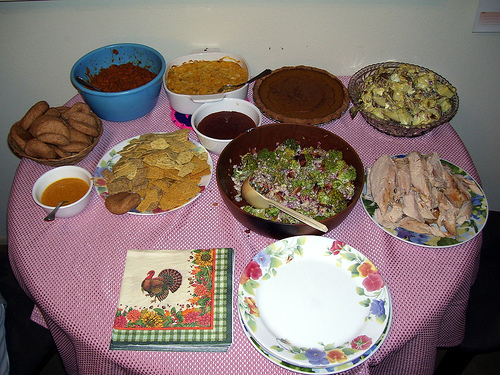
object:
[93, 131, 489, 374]
plate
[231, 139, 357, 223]
flowers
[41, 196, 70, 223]
spoon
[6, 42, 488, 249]
food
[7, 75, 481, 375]
table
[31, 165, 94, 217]
cup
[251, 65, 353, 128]
pie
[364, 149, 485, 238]
meat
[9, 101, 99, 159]
roll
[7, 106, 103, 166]
basket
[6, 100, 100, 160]
bread rolls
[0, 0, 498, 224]
wall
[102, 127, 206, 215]
cracker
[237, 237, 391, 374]
flowers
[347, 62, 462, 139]
dish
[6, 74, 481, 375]
cloth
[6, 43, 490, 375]
bowl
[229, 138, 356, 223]
salad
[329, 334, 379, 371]
pile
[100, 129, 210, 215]
snack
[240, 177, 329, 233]
spoon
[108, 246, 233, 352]
napkins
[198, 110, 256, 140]
liquid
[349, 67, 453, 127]
vegetables